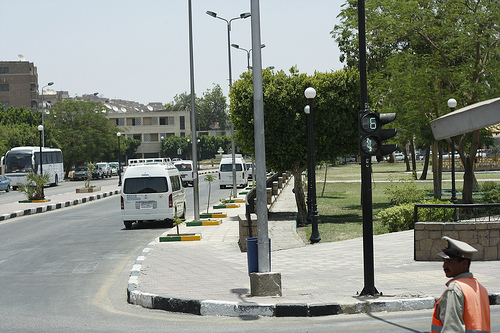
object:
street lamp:
[206, 0, 251, 199]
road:
[6, 175, 231, 328]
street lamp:
[186, 1, 199, 227]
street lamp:
[233, 38, 264, 187]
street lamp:
[36, 120, 48, 206]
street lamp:
[116, 126, 123, 192]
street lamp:
[160, 132, 167, 165]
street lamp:
[185, 138, 190, 174]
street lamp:
[196, 134, 202, 169]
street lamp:
[307, 86, 319, 248]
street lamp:
[304, 104, 315, 244]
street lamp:
[445, 94, 462, 221]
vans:
[122, 152, 246, 227]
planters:
[20, 199, 51, 204]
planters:
[161, 236, 196, 243]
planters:
[186, 220, 224, 225]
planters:
[202, 213, 227, 218]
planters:
[214, 205, 241, 210]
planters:
[222, 200, 249, 203]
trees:
[24, 175, 49, 199]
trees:
[169, 204, 185, 238]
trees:
[201, 169, 214, 215]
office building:
[46, 98, 193, 156]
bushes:
[162, 137, 231, 154]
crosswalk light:
[355, 107, 393, 164]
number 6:
[368, 115, 379, 131]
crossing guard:
[419, 234, 490, 331]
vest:
[429, 278, 493, 332]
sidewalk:
[145, 240, 499, 295]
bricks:
[177, 262, 216, 291]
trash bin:
[243, 236, 277, 278]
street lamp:
[253, 4, 270, 294]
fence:
[235, 168, 283, 253]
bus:
[2, 142, 66, 191]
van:
[122, 154, 188, 224]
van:
[170, 157, 199, 187]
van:
[217, 153, 247, 190]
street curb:
[124, 299, 427, 314]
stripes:
[153, 300, 282, 317]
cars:
[71, 158, 121, 180]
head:
[442, 256, 472, 279]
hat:
[437, 234, 480, 264]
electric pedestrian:
[360, 137, 376, 155]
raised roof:
[128, 158, 174, 170]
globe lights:
[35, 125, 47, 133]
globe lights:
[115, 130, 124, 139]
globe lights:
[159, 136, 166, 143]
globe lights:
[186, 137, 191, 144]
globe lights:
[198, 139, 205, 145]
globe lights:
[303, 83, 320, 104]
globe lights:
[303, 103, 315, 117]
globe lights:
[444, 95, 459, 112]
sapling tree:
[245, 63, 354, 235]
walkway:
[272, 182, 296, 249]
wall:
[416, 224, 499, 259]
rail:
[416, 203, 500, 227]